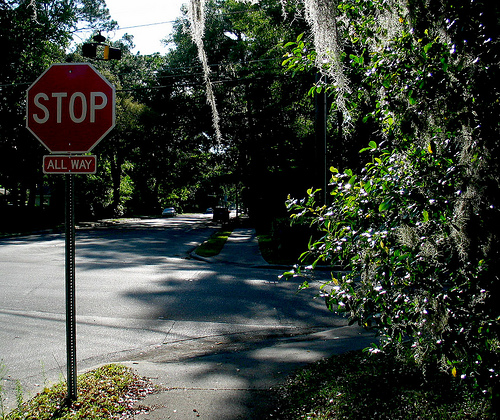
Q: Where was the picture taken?
A: It was taken at the street.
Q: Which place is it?
A: It is a street.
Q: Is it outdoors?
A: Yes, it is outdoors.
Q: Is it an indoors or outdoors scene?
A: It is outdoors.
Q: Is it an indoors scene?
A: No, it is outdoors.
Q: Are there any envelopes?
A: No, there are no envelopes.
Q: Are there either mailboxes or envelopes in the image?
A: No, there are no envelopes or mailboxes.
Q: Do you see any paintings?
A: No, there are no paintings.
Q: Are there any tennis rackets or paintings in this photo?
A: No, there are no paintings or tennis rackets.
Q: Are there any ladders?
A: No, there are no ladders.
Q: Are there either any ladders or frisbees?
A: No, there are no ladders or frisbees.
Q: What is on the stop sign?
A: The letter is on the stop sign.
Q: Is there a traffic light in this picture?
A: Yes, there is a traffic light.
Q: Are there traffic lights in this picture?
A: Yes, there is a traffic light.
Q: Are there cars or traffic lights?
A: Yes, there is a traffic light.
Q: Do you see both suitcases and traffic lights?
A: No, there is a traffic light but no suitcases.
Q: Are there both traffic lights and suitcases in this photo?
A: No, there is a traffic light but no suitcases.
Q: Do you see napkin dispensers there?
A: No, there are no napkin dispensers.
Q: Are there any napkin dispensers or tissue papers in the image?
A: No, there are no napkin dispensers or tissue papers.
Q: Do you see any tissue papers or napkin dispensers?
A: No, there are no napkin dispensers or tissue papers.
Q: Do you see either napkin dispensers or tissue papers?
A: No, there are no napkin dispensers or tissue papers.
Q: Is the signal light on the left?
A: Yes, the signal light is on the left of the image.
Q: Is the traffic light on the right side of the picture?
A: No, the traffic light is on the left of the image.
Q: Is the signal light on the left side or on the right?
A: The signal light is on the left of the image.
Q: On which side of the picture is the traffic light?
A: The traffic light is on the left of the image.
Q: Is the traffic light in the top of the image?
A: Yes, the traffic light is in the top of the image.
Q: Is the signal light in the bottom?
A: No, the signal light is in the top of the image.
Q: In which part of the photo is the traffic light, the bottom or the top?
A: The traffic light is in the top of the image.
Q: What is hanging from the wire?
A: The traffic light is hanging from the wire.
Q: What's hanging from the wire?
A: The traffic light is hanging from the wire.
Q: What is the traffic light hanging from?
A: The traffic light is hanging from the wire.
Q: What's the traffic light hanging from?
A: The traffic light is hanging from the wire.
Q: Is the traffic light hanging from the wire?
A: Yes, the traffic light is hanging from the wire.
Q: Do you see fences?
A: No, there are no fences.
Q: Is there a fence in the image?
A: No, there are no fences.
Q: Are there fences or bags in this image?
A: No, there are no fences or bags.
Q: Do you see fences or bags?
A: No, there are no fences or bags.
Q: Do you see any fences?
A: No, there are no fences.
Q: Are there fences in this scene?
A: No, there are no fences.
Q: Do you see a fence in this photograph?
A: No, there are no fences.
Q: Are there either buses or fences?
A: No, there are no fences or buses.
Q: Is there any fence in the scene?
A: No, there are no fences.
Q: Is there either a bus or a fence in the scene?
A: No, there are no fences or buses.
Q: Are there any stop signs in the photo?
A: Yes, there is a stop sign.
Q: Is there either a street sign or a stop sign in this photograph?
A: Yes, there is a stop sign.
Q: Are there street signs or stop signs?
A: Yes, there is a stop sign.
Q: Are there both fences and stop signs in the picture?
A: No, there is a stop sign but no fences.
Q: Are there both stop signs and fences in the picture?
A: No, there is a stop sign but no fences.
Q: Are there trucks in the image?
A: No, there are no trucks.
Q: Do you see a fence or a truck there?
A: No, there are no trucks or fences.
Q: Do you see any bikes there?
A: No, there are no bikes.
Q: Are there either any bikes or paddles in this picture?
A: No, there are no bikes or paddles.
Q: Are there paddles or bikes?
A: No, there are no bikes or paddles.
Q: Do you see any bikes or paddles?
A: No, there are no bikes or paddles.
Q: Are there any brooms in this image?
A: No, there are no brooms.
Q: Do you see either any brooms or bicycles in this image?
A: No, there are no brooms or bicycles.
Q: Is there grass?
A: Yes, there is grass.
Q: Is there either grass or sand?
A: Yes, there is grass.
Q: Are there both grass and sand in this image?
A: No, there is grass but no sand.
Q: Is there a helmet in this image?
A: No, there are no helmets.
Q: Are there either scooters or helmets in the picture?
A: No, there are no helmets or scooters.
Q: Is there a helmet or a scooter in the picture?
A: No, there are no helmets or scooters.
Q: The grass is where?
A: The grass is on the sidewalk.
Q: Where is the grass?
A: The grass is on the sidewalk.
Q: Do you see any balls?
A: No, there are no balls.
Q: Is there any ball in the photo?
A: No, there are no balls.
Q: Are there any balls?
A: No, there are no balls.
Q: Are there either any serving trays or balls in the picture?
A: No, there are no balls or serving trays.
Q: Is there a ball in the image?
A: No, there are no balls.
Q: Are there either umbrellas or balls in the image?
A: No, there are no balls or umbrellas.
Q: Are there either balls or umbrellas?
A: No, there are no balls or umbrellas.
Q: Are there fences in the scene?
A: No, there are no fences.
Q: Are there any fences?
A: No, there are no fences.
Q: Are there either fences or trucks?
A: No, there are no fences or trucks.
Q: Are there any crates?
A: No, there are no crates.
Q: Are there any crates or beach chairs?
A: No, there are no crates or beach chairs.